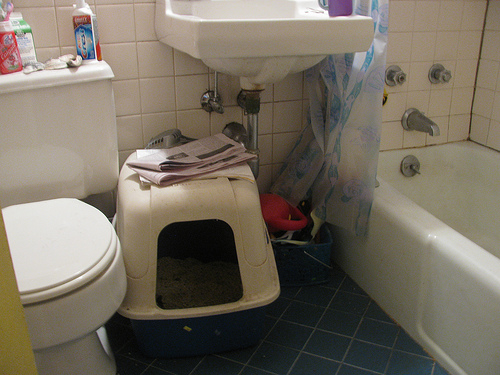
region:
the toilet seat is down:
[1, 199, 116, 306]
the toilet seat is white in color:
[1, 198, 116, 308]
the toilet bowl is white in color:
[1, 197, 126, 370]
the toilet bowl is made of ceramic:
[4, 203, 126, 370]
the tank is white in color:
[3, 60, 119, 196]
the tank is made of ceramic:
[2, 60, 129, 198]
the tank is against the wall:
[1, 60, 127, 207]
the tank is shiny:
[1, 56, 116, 206]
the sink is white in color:
[153, 0, 372, 91]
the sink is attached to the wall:
[155, 3, 376, 87]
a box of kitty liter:
[117, 154, 309, 359]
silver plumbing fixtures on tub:
[386, 50, 479, 190]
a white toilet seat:
[2, 63, 160, 373]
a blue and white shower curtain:
[305, 53, 396, 236]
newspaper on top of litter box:
[120, 107, 276, 211]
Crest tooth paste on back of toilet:
[70, 5, 117, 67]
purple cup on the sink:
[322, 0, 361, 26]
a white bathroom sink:
[158, 5, 365, 100]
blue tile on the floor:
[103, 230, 476, 373]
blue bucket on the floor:
[288, 204, 367, 290]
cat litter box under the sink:
[115, 150, 280, 350]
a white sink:
[157, 4, 374, 94]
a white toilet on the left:
[0, 58, 137, 373]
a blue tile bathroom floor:
[125, 280, 450, 374]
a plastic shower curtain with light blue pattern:
[278, 7, 385, 239]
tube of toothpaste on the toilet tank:
[73, 5, 96, 62]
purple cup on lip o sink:
[323, 2, 351, 16]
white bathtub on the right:
[335, 142, 498, 374]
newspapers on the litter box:
[127, 137, 256, 187]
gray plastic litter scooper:
[142, 130, 195, 147]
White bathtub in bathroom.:
[328, 139, 499, 374]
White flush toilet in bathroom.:
[0, 58, 128, 373]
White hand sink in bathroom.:
[155, 0, 375, 91]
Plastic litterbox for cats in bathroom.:
[111, 148, 281, 360]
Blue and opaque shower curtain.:
[268, 0, 388, 237]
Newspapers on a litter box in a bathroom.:
[126, 132, 257, 184]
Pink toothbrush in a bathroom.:
[3, 2, 13, 22]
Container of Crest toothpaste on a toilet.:
[71, 0, 97, 63]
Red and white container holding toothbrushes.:
[0, 20, 22, 72]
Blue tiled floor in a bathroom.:
[104, 258, 450, 374]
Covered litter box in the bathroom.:
[114, 140, 284, 354]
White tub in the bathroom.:
[325, 139, 497, 373]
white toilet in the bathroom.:
[0, 56, 127, 373]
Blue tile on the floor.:
[103, 268, 452, 374]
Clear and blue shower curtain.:
[267, 0, 389, 240]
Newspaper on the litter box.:
[122, 131, 256, 189]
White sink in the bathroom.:
[150, 2, 375, 94]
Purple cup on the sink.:
[324, 1, 356, 18]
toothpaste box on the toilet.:
[69, 10, 101, 70]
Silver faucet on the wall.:
[400, 107, 443, 138]